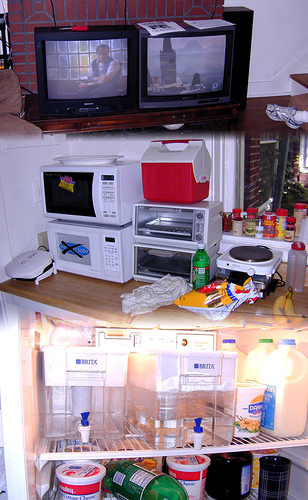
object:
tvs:
[33, 24, 236, 118]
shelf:
[25, 89, 295, 133]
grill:
[3, 250, 57, 285]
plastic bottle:
[286, 241, 307, 293]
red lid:
[291, 240, 306, 250]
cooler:
[140, 137, 211, 203]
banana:
[272, 291, 306, 330]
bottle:
[245, 207, 258, 235]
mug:
[257, 456, 291, 498]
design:
[259, 469, 288, 498]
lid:
[273, 339, 296, 349]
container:
[234, 379, 268, 438]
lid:
[140, 137, 213, 184]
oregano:
[245, 215, 256, 236]